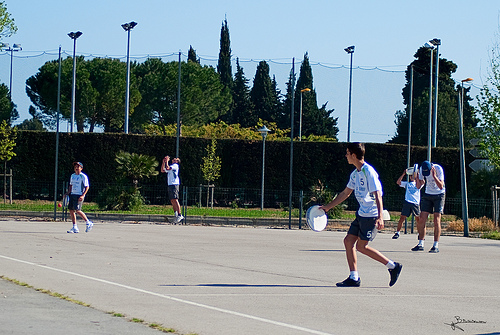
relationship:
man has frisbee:
[318, 141, 403, 288] [305, 205, 327, 232]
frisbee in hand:
[305, 205, 327, 232] [316, 204, 330, 214]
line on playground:
[1, 255, 330, 335] [0, 209, 499, 333]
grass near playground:
[1, 198, 499, 240] [0, 209, 499, 333]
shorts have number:
[345, 211, 381, 241] [365, 230, 373, 240]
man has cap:
[411, 160, 446, 252] [421, 160, 433, 176]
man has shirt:
[318, 141, 403, 288] [343, 166, 386, 218]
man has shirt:
[411, 160, 446, 252] [415, 164, 445, 193]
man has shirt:
[160, 154, 185, 226] [167, 165, 179, 188]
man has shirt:
[66, 162, 94, 235] [69, 173, 90, 194]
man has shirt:
[392, 166, 426, 241] [400, 180, 423, 202]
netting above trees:
[0, 52, 499, 149] [0, 1, 499, 206]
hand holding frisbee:
[316, 204, 330, 214] [305, 205, 327, 232]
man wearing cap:
[411, 160, 446, 252] [421, 160, 433, 176]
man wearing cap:
[66, 162, 94, 235] [73, 162, 83, 168]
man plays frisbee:
[318, 141, 403, 288] [305, 205, 327, 232]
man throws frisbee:
[318, 141, 403, 288] [305, 205, 327, 232]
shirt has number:
[343, 166, 386, 218] [358, 177, 365, 186]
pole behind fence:
[2, 43, 22, 133] [0, 186, 499, 234]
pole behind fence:
[51, 48, 67, 219] [0, 186, 499, 234]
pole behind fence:
[120, 21, 137, 134] [0, 186, 499, 234]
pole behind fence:
[175, 52, 182, 159] [0, 186, 499, 234]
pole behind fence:
[287, 56, 296, 228] [0, 186, 499, 234]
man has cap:
[66, 162, 94, 235] [421, 160, 433, 176]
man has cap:
[411, 160, 446, 252] [73, 162, 83, 168]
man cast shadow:
[318, 141, 403, 288] [160, 283, 337, 289]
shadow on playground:
[160, 283, 337, 289] [0, 209, 499, 333]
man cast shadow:
[411, 160, 446, 252] [299, 249, 417, 254]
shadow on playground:
[299, 249, 417, 254] [0, 209, 499, 333]